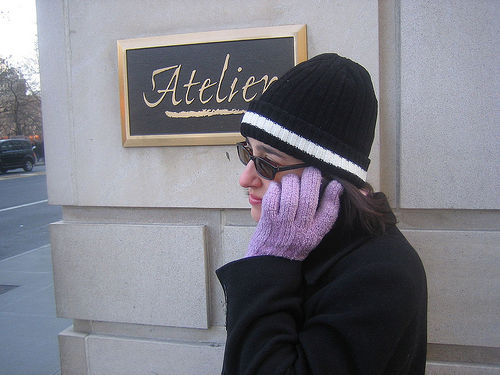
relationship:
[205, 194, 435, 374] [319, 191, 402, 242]
black coat with collar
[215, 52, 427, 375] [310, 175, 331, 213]
lady talking on phone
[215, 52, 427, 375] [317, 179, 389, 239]
lady with hair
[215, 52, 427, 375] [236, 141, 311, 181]
lady wearing glasses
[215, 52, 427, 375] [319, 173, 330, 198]
lady talking on phone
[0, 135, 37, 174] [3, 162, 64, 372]
black car on street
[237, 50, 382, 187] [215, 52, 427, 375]
hat on lady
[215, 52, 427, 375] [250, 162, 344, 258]
lady wearing glove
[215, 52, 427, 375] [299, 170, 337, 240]
lady talking on phone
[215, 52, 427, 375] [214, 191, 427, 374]
lady wearing black coat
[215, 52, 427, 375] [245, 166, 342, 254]
lady wearing glove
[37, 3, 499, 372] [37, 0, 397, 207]
building made of bricks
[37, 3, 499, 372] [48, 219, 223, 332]
building made of bricks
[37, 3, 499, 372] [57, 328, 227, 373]
building made of bricks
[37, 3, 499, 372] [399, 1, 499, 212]
building made of bricks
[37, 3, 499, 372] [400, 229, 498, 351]
building made of bricks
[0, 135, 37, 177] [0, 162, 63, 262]
black car on road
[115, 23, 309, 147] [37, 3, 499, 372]
sign on building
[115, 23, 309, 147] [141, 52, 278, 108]
sign with letters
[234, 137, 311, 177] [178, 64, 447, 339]
glasses on face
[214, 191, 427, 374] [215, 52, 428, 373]
black coat worn by lady